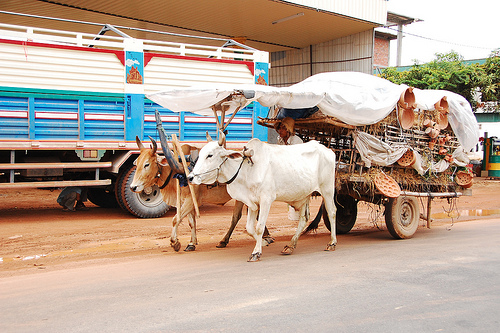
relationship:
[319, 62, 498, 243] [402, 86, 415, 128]
cart carrying pottery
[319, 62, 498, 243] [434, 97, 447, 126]
cart carrying pottery